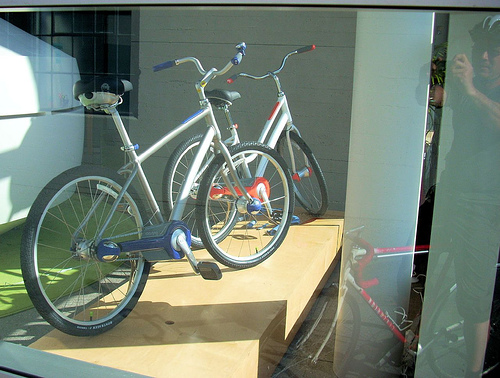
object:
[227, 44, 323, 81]
handlebars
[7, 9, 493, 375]
window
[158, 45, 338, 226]
bicycle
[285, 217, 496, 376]
bicycle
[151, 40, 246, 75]
handle bars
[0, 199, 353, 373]
ground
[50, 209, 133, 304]
spoke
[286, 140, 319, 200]
spoke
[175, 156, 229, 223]
spoke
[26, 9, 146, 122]
window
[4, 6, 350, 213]
house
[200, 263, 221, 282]
paddle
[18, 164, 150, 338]
bike wheel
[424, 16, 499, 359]
man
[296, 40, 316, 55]
bike grip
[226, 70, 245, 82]
bike grip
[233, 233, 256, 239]
shadow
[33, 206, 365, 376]
platform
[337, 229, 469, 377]
reflection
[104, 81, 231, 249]
frame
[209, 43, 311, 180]
frame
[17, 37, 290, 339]
bicycle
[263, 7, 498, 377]
reflection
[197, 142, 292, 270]
rubber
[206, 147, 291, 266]
tire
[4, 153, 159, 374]
wheel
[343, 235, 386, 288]
bike grip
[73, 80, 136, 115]
seat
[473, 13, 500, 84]
head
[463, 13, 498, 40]
reflection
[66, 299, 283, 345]
shadow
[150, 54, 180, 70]
bike grip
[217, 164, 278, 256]
spoke